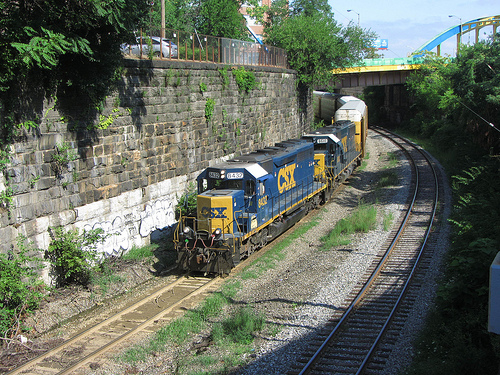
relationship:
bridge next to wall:
[313, 50, 451, 92] [300, 44, 455, 168]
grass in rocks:
[201, 310, 260, 350] [261, 261, 315, 336]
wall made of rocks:
[0, 59, 421, 298] [138, 69, 276, 232]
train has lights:
[172, 89, 369, 279] [211, 226, 223, 238]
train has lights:
[172, 89, 369, 279] [182, 225, 189, 234]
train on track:
[142, 78, 412, 290] [105, 303, 148, 340]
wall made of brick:
[0, 59, 421, 298] [118, 125, 188, 172]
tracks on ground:
[7, 275, 220, 375] [58, 275, 481, 358]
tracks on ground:
[23, 283, 208, 373] [58, 275, 481, 358]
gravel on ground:
[282, 271, 329, 307] [124, 221, 364, 373]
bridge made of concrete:
[314, 16, 500, 91] [330, 75, 420, 87]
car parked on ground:
[119, 34, 180, 56] [0, 125, 500, 375]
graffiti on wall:
[92, 201, 162, 248] [16, 59, 277, 153]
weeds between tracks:
[299, 204, 401, 255] [141, 288, 401, 348]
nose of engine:
[201, 190, 231, 238] [166, 137, 323, 274]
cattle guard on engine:
[164, 226, 256, 281] [152, 213, 249, 293]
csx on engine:
[276, 163, 295, 192] [175, 151, 364, 274]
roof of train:
[333, 89, 367, 131] [141, 86, 396, 279]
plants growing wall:
[200, 59, 304, 104] [45, 55, 188, 223]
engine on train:
[305, 116, 358, 188] [159, 90, 392, 272]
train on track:
[172, 89, 369, 279] [12, 109, 457, 371]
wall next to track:
[6, 51, 304, 296] [172, 123, 336, 273]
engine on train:
[175, 151, 364, 274] [172, 89, 369, 279]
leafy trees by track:
[403, 32, 498, 110] [287, 123, 446, 373]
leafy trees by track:
[243, 0, 380, 93] [1, 164, 360, 374]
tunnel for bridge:
[378, 83, 415, 123] [322, 17, 484, 90]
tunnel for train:
[368, 82, 413, 130] [172, 89, 369, 279]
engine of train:
[175, 151, 364, 274] [142, 94, 331, 284]